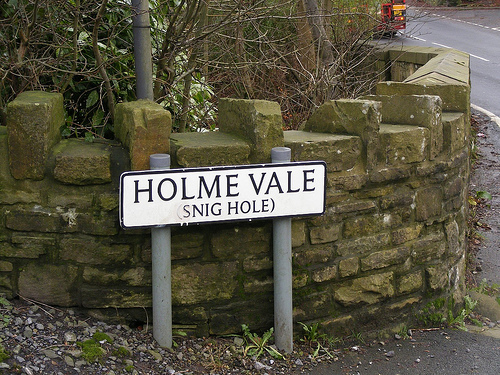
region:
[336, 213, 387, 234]
brick on the container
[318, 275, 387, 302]
brick on the container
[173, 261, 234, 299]
brick on the container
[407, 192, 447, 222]
brick on the container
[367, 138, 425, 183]
brick on the container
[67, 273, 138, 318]
brick on the container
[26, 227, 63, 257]
brick on the container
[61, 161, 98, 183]
brick on the container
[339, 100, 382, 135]
brick on the container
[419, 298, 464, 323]
brick on the container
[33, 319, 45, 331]
A pebble on the ground.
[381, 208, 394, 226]
A white spot on the wall.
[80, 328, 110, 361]
Green moss on the ground.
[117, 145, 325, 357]
A sign in front of the wall.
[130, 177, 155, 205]
The letter H on a sign.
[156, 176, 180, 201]
The letter O on a sign.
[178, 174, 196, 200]
The letter L on a sign.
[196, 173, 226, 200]
The letter M on a sign.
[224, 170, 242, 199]
The letter E on a sign.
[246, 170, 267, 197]
The letter V on a sign.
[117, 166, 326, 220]
a white sign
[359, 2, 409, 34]
a red bus on the stree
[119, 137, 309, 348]
a sign in the ground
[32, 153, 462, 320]
a stone wall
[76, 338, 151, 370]
moss on the ground in the rocks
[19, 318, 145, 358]
rocks on the ground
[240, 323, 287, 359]
weeds on the ground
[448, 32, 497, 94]
the street with white lines painted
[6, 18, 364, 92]
branches of the trees behind the stone wall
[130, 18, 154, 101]
a steel pipe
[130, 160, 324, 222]
this is a signpost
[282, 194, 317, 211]
the post is white in color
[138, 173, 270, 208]
this is a writing in color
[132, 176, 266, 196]
the writing is in black in color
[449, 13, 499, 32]
this is the road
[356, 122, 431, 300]
this is a wall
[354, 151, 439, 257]
the wall is brown in color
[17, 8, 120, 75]
this is a tree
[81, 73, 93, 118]
the leaves are greenin color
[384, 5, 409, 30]
this is a lorry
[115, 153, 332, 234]
a white steel plate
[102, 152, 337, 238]
a white steel plate traffic sign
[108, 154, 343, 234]
a street sign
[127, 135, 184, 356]
a steel pole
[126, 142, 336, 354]
street sign on two steel pole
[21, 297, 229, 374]
rock and debris on floor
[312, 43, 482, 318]
brick walls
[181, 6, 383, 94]
bunch of tree branches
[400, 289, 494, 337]
weed grasses on edge of wall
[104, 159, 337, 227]
characters on a white plate